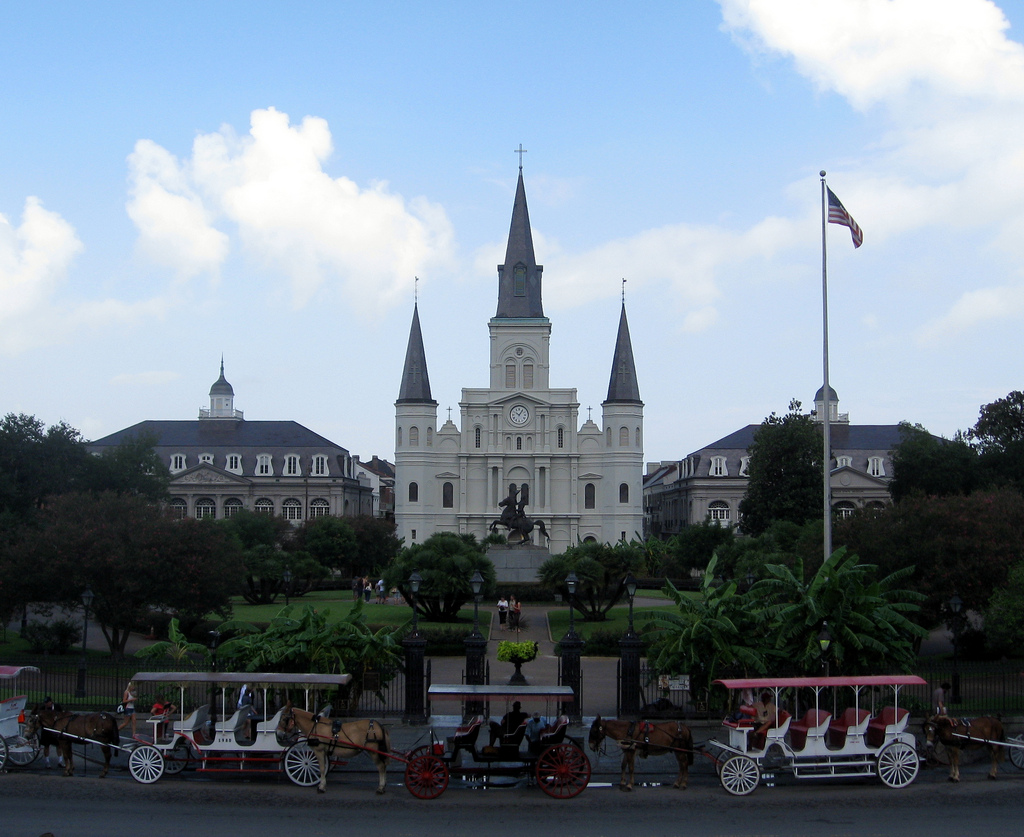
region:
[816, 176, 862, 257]
american flag hanging on gray pole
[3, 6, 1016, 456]
light blue cloudy sky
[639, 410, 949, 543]
big house at right side of castle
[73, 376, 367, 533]
big house at left side of castle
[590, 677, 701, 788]
brown horse pulling pink and white car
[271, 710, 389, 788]
brown horse pulling burgundy and white car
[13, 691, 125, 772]
brown horse pulling white car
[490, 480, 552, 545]
big horse statue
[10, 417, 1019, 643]
a bunch of tree with green leaves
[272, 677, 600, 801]
horse hitched to carriage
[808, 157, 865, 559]
American flag on the flag pole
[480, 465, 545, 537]
statue in front of building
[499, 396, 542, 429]
clock on the front of building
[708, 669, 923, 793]
carriage is white and red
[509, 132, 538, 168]
cross on top of steeple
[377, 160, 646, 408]
steeples are round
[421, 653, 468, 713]
opening in the gate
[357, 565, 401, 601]
people walking around the statue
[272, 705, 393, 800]
horse is tan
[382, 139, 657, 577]
the building has three towers and a clock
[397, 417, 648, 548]
arched windows are on the building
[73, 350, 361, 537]
the building has a tower with a dome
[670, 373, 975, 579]
the building has a dome behind the flagpole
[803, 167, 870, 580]
an American flag is on a pole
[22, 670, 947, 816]
horse drawn carriages are parked at the gates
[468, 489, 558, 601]
a bronze statue is in the center of a park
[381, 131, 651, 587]
beautiful church in the country side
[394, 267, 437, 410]
steeple of church in country side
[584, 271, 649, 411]
steeple of church in country side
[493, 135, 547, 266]
steeple of church in country side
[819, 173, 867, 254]
flag flying high on flag pole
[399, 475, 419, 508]
window of church in country side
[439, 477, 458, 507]
window of church in country side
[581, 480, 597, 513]
window of church in country side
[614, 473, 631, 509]
window of church in country side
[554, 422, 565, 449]
window of church in country side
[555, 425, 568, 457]
building has a window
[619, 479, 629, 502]
building has a window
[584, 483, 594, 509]
building has a window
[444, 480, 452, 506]
building has a window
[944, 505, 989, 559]
green leaves on the tree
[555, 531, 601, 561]
green leaves on the tree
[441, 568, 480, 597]
green leaves on the tree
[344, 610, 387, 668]
green leaves on the tree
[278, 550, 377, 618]
green leaves on the tree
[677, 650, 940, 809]
cart being pulled by horse